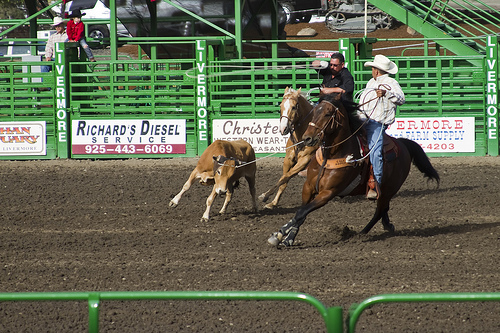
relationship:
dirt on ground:
[37, 204, 126, 269] [24, 171, 176, 280]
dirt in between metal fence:
[0, 154, 500, 333] [0, 290, 500, 333]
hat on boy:
[361, 53, 396, 75] [44, 6, 96, 62]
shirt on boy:
[62, 13, 92, 53] [44, 6, 96, 62]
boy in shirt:
[59, 11, 88, 60] [55, 13, 89, 51]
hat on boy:
[61, 8, 91, 20] [59, 11, 88, 60]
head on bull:
[212, 155, 246, 198] [167, 139, 259, 223]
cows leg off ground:
[155, 164, 205, 214] [6, 160, 493, 330]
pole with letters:
[190, 36, 209, 166] [191, 39, 205, 143]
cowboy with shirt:
[356, 53, 405, 200] [63, 9, 86, 43]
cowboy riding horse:
[353, 46, 405, 204] [261, 86, 444, 264]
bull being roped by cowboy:
[167, 139, 259, 223] [344, 41, 412, 222]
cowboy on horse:
[356, 53, 405, 200] [269, 81, 456, 260]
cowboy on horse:
[356, 53, 405, 200] [257, 72, 334, 226]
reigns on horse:
[307, 72, 387, 160] [250, 95, 453, 250]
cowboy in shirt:
[356, 53, 405, 200] [311, 55, 358, 115]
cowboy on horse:
[356, 53, 405, 200] [275, 69, 464, 249]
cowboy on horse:
[356, 53, 405, 200] [259, 50, 340, 220]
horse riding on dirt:
[265, 87, 440, 247] [0, 154, 500, 333]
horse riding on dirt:
[258, 79, 327, 214] [0, 154, 500, 333]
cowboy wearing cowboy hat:
[356, 53, 405, 200] [353, 39, 409, 86]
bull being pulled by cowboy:
[161, 120, 271, 233] [356, 53, 405, 200]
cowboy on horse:
[356, 53, 405, 200] [249, 77, 458, 247]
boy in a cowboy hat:
[62, 9, 97, 63] [61, 3, 91, 28]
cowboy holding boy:
[356, 53, 405, 200] [57, 11, 98, 70]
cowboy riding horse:
[356, 53, 405, 200] [266, 66, 444, 256]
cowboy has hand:
[356, 53, 405, 200] [373, 88, 384, 98]